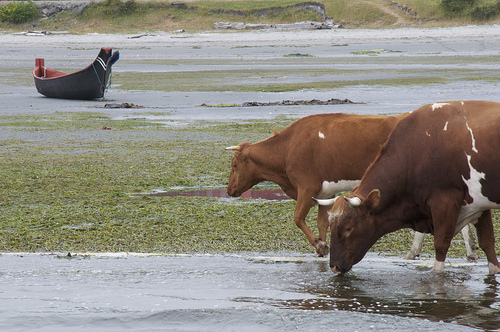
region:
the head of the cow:
[226, 138, 258, 198]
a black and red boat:
[30, 40, 118, 105]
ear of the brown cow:
[361, 184, 382, 211]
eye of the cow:
[341, 225, 358, 235]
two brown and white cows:
[185, 102, 497, 282]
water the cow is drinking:
[1, 239, 477, 329]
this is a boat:
[22, 37, 142, 117]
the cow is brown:
[200, 92, 427, 264]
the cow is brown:
[320, 98, 496, 279]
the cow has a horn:
[329, 183, 382, 230]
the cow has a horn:
[300, 183, 345, 216]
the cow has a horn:
[168, 145, 244, 185]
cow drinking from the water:
[316, 103, 498, 275]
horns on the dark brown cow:
[306, 188, 364, 207]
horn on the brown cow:
[223, 141, 235, 156]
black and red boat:
[29, 40, 119, 102]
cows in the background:
[196, 82, 468, 329]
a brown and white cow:
[295, 69, 497, 326]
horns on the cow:
[299, 106, 410, 323]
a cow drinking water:
[270, 100, 491, 304]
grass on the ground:
[44, 120, 307, 287]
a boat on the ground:
[14, 32, 187, 139]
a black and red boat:
[6, 25, 160, 133]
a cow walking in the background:
[205, 104, 465, 276]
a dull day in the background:
[8, 4, 487, 311]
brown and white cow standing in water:
[310, 99, 499, 279]